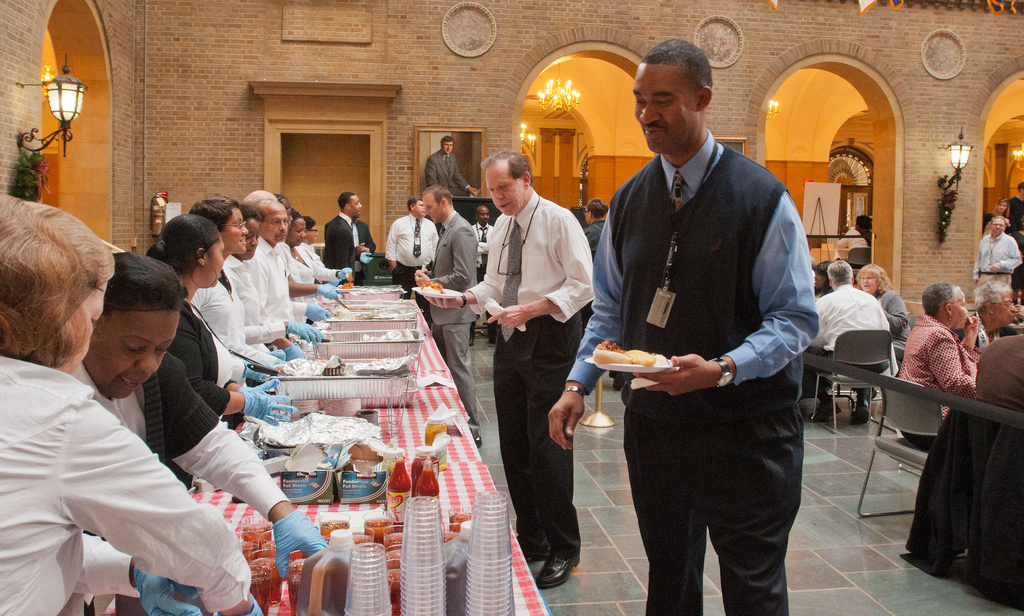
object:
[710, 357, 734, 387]
watch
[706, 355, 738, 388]
wrist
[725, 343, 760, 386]
cuff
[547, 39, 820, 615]
man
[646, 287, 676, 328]
badge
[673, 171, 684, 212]
tie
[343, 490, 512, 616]
cups in stack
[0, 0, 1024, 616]
room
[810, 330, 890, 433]
grey chair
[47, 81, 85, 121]
light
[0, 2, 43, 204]
wall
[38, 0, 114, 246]
arch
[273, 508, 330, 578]
hand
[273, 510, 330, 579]
blue glove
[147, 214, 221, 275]
hair net on head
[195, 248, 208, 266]
ear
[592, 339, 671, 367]
plate of food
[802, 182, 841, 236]
picture on wall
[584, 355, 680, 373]
plate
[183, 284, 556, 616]
table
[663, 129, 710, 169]
neck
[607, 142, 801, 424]
vest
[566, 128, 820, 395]
shirt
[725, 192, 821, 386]
sleeve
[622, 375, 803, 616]
pants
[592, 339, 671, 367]
food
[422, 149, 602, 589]
man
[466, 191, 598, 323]
shirt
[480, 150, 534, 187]
hair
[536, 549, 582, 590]
shoes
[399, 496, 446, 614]
cups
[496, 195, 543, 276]
glasses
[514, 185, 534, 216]
neck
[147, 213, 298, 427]
woman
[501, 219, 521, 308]
tie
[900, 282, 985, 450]
woman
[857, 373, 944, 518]
chair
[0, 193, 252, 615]
people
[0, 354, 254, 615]
shirts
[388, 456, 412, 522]
bottle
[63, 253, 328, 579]
woman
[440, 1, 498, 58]
decoration